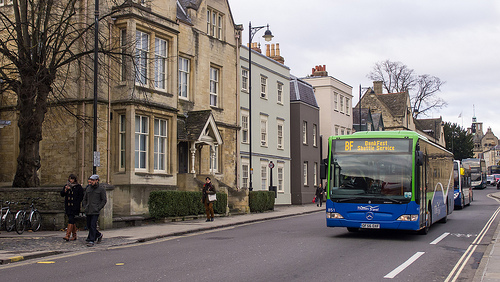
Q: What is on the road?
A: Bus.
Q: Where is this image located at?
A: Residential area.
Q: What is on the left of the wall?
A: Tree.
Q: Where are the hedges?
A: In front of the residence.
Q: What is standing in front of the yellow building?
A: A person.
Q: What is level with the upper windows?
A: Street lamp.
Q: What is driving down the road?
A: Bus.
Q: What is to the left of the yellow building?
A: A tree.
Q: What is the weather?
A: Cloudy.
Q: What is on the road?
A: White lines.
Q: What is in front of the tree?
A: Bikes.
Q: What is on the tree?
A: Bare tree.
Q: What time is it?
A: Afternoon.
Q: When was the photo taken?
A: Outside somewhere.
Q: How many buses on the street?
A: Three.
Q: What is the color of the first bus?
A: Blue and green.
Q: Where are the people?
A: On the sidewalk.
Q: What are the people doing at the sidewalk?
A: Walking.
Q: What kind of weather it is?
A: Cold and cloudy.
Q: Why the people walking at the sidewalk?
A: To be safer.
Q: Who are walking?
A: People.